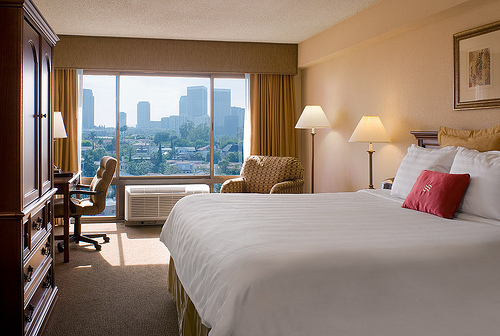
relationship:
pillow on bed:
[403, 168, 470, 220] [165, 125, 495, 334]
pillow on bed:
[432, 126, 499, 154] [165, 125, 495, 334]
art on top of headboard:
[453, 17, 499, 110] [408, 129, 440, 149]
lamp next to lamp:
[351, 107, 391, 194] [291, 102, 331, 192]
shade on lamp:
[347, 113, 394, 147] [351, 107, 391, 194]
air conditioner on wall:
[123, 181, 215, 224] [115, 175, 215, 225]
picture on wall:
[439, 19, 498, 115] [307, 2, 498, 191]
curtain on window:
[248, 73, 303, 157] [76, 70, 254, 216]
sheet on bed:
[159, 190, 499, 334] [165, 125, 495, 334]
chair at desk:
[47, 151, 119, 262] [54, 166, 84, 270]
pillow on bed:
[450, 144, 499, 220] [165, 125, 495, 334]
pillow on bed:
[386, 143, 456, 206] [165, 125, 495, 334]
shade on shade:
[347, 113, 394, 147] [295, 104, 335, 133]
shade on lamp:
[295, 104, 335, 133] [291, 102, 331, 192]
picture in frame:
[467, 47, 495, 86] [453, 18, 499, 112]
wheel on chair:
[55, 244, 65, 251] [47, 151, 119, 262]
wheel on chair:
[104, 236, 109, 242] [47, 151, 119, 262]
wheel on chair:
[95, 243, 102, 251] [47, 151, 119, 262]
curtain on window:
[52, 67, 80, 178] [75, 70, 253, 219]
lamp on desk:
[53, 110, 78, 169] [59, 159, 86, 226]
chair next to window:
[221, 150, 306, 196] [75, 70, 253, 219]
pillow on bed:
[403, 168, 470, 220] [236, 216, 390, 296]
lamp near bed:
[351, 107, 391, 194] [289, 206, 359, 262]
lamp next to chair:
[291, 102, 331, 192] [221, 150, 306, 196]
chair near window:
[221, 150, 306, 196] [75, 70, 253, 219]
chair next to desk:
[47, 151, 119, 262] [58, 172, 71, 204]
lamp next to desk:
[60, 172, 81, 241] [51, 99, 83, 177]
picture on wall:
[412, 40, 498, 141] [291, 2, 497, 192]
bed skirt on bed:
[158, 284, 189, 324] [165, 125, 495, 334]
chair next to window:
[221, 150, 296, 196] [75, 70, 253, 219]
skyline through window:
[81, 82, 247, 170] [75, 70, 253, 219]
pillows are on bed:
[390, 132, 499, 220] [146, 139, 492, 334]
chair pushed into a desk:
[47, 151, 119, 262] [45, 162, 85, 254]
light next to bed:
[287, 99, 330, 189] [165, 125, 495, 334]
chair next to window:
[47, 151, 119, 262] [75, 70, 253, 219]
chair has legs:
[47, 151, 119, 262] [42, 210, 108, 255]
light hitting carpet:
[69, 208, 178, 276] [40, 212, 197, 333]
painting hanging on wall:
[446, 8, 498, 109] [291, 2, 497, 192]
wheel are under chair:
[55, 244, 65, 251] [47, 151, 119, 262]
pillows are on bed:
[390, 132, 499, 220] [165, 125, 495, 334]